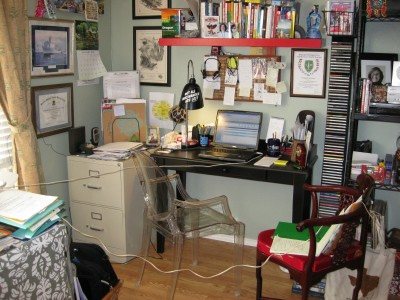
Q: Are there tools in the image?
A: No, there are no tools.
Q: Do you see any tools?
A: No, there are no tools.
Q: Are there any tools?
A: No, there are no tools.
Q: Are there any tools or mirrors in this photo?
A: No, there are no tools or mirrors.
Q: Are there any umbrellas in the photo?
A: No, there are no umbrellas.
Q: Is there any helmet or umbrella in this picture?
A: No, there are no umbrellas or helmets.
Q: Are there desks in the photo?
A: Yes, there is a desk.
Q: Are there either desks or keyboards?
A: Yes, there is a desk.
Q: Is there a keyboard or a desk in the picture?
A: Yes, there is a desk.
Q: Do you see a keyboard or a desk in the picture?
A: Yes, there is a desk.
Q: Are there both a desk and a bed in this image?
A: No, there is a desk but no beds.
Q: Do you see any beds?
A: No, there are no beds.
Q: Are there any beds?
A: No, there are no beds.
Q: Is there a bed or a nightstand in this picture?
A: No, there are no beds or nightstands.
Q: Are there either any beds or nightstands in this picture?
A: No, there are no beds or nightstands.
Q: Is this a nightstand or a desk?
A: This is a desk.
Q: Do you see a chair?
A: Yes, there is a chair.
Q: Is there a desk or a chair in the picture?
A: Yes, there is a chair.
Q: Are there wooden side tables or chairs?
A: Yes, there is a wood chair.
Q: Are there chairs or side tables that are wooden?
A: Yes, the chair is wooden.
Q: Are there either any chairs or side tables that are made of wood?
A: Yes, the chair is made of wood.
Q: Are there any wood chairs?
A: Yes, there is a wood chair.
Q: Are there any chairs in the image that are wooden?
A: Yes, there is a chair that is wooden.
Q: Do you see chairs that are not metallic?
A: Yes, there is a wooden chair.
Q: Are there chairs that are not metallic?
A: Yes, there is a wooden chair.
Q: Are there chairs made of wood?
A: Yes, there is a chair that is made of wood.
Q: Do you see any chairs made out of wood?
A: Yes, there is a chair that is made of wood.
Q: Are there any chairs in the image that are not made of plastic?
A: Yes, there is a chair that is made of wood.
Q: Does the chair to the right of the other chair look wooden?
A: Yes, the chair is wooden.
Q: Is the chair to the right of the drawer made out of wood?
A: Yes, the chair is made of wood.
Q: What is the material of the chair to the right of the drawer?
A: The chair is made of wood.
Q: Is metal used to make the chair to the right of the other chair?
A: No, the chair is made of wood.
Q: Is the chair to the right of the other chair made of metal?
A: No, the chair is made of wood.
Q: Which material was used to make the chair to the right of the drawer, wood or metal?
A: The chair is made of wood.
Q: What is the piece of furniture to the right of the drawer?
A: The piece of furniture is a chair.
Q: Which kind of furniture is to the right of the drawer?
A: The piece of furniture is a chair.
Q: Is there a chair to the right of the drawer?
A: Yes, there is a chair to the right of the drawer.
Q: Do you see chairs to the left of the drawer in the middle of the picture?
A: No, the chair is to the right of the drawer.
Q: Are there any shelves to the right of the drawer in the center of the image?
A: No, there is a chair to the right of the drawer.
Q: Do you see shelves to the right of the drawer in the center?
A: No, there is a chair to the right of the drawer.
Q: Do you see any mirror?
A: No, there are no mirrors.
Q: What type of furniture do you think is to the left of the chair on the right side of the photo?
A: The piece of furniture is a drawer.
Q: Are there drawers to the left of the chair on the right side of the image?
A: Yes, there is a drawer to the left of the chair.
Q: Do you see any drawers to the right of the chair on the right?
A: No, the drawer is to the left of the chair.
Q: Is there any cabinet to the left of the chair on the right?
A: No, there is a drawer to the left of the chair.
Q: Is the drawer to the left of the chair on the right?
A: Yes, the drawer is to the left of the chair.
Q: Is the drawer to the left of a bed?
A: No, the drawer is to the left of the chair.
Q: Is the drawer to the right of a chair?
A: No, the drawer is to the left of a chair.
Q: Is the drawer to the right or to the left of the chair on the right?
A: The drawer is to the left of the chair.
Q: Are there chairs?
A: Yes, there is a chair.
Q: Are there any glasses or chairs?
A: Yes, there is a chair.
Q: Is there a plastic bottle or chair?
A: Yes, there is a plastic chair.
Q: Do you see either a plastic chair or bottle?
A: Yes, there is a plastic chair.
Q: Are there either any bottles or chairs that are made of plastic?
A: Yes, the chair is made of plastic.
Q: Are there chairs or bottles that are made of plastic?
A: Yes, the chair is made of plastic.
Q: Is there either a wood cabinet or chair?
A: Yes, there is a wood chair.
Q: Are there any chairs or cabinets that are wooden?
A: Yes, the chair is wooden.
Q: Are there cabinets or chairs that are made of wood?
A: Yes, the chair is made of wood.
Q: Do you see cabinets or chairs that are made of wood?
A: Yes, the chair is made of wood.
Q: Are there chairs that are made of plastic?
A: Yes, there is a chair that is made of plastic.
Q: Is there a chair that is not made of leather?
A: Yes, there is a chair that is made of plastic.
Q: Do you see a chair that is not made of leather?
A: Yes, there is a chair that is made of plastic.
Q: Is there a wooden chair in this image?
A: Yes, there is a wood chair.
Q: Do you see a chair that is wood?
A: Yes, there is a wood chair.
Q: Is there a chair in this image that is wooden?
A: Yes, there is a chair that is wooden.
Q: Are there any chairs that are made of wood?
A: Yes, there is a chair that is made of wood.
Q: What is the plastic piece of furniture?
A: The piece of furniture is a chair.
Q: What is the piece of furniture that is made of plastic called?
A: The piece of furniture is a chair.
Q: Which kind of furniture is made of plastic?
A: The furniture is a chair.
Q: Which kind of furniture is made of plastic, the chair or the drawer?
A: The chair is made of plastic.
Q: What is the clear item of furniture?
A: The piece of furniture is a chair.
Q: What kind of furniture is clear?
A: The furniture is a chair.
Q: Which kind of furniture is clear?
A: The furniture is a chair.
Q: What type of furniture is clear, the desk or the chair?
A: The chair is clear.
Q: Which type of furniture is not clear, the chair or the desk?
A: The desk is not clear.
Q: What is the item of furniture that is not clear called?
A: The piece of furniture is a desk.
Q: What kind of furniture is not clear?
A: The furniture is a desk.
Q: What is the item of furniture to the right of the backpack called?
A: The piece of furniture is a chair.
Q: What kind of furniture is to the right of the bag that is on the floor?
A: The piece of furniture is a chair.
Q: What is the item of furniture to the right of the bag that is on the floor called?
A: The piece of furniture is a chair.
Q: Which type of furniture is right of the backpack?
A: The piece of furniture is a chair.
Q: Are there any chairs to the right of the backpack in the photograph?
A: Yes, there is a chair to the right of the backpack.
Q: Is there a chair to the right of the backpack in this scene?
A: Yes, there is a chair to the right of the backpack.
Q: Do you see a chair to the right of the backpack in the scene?
A: Yes, there is a chair to the right of the backpack.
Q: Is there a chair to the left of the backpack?
A: No, the chair is to the right of the backpack.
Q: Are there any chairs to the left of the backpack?
A: No, the chair is to the right of the backpack.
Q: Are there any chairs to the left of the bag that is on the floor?
A: No, the chair is to the right of the backpack.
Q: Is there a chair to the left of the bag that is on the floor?
A: No, the chair is to the right of the backpack.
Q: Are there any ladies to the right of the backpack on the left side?
A: No, there is a chair to the right of the backpack.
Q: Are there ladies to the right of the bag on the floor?
A: No, there is a chair to the right of the backpack.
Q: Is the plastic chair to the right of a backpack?
A: Yes, the chair is to the right of a backpack.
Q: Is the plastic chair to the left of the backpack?
A: No, the chair is to the right of the backpack.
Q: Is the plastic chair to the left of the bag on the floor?
A: No, the chair is to the right of the backpack.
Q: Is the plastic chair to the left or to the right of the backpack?
A: The chair is to the right of the backpack.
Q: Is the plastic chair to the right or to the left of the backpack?
A: The chair is to the right of the backpack.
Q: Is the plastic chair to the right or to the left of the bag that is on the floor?
A: The chair is to the right of the backpack.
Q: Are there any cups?
A: Yes, there is a cup.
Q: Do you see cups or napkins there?
A: Yes, there is a cup.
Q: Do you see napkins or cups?
A: Yes, there is a cup.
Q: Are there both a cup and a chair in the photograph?
A: Yes, there are both a cup and a chair.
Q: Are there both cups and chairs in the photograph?
A: Yes, there are both a cup and a chair.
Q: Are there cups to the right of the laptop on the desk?
A: Yes, there is a cup to the right of the laptop.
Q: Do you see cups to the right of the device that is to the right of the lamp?
A: Yes, there is a cup to the right of the laptop.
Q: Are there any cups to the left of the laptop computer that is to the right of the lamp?
A: No, the cup is to the right of the laptop.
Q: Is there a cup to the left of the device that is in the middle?
A: No, the cup is to the right of the laptop.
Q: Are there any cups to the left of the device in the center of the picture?
A: No, the cup is to the right of the laptop.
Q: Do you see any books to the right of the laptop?
A: No, there is a cup to the right of the laptop.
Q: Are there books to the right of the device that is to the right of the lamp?
A: No, there is a cup to the right of the laptop.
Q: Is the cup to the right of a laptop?
A: Yes, the cup is to the right of a laptop.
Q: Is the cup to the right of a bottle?
A: No, the cup is to the right of a laptop.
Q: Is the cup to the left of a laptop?
A: No, the cup is to the right of a laptop.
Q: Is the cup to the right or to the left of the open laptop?
A: The cup is to the right of the laptop.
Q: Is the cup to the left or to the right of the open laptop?
A: The cup is to the right of the laptop.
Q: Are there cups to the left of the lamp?
A: No, the cup is to the right of the lamp.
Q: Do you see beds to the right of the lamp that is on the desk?
A: No, there is a cup to the right of the lamp.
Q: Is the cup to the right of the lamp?
A: Yes, the cup is to the right of the lamp.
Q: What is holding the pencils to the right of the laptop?
A: The cup is holding the pencils.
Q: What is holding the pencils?
A: The cup is holding the pencils.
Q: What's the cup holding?
A: The cup is holding the pencils.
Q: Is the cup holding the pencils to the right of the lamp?
A: Yes, the cup is holding the pencils.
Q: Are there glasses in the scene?
A: No, there are no glasses.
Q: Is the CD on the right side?
A: Yes, the CD is on the right of the image.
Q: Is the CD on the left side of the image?
A: No, the CD is on the right of the image.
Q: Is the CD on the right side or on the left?
A: The CD is on the right of the image.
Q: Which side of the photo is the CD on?
A: The CD is on the right of the image.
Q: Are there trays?
A: No, there are no trays.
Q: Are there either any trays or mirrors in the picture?
A: No, there are no trays or mirrors.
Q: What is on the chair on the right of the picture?
A: The seat is on the chair.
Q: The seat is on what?
A: The seat is on the chair.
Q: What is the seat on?
A: The seat is on the chair.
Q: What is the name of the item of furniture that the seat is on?
A: The piece of furniture is a chair.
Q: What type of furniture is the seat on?
A: The seat is on the chair.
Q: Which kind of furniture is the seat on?
A: The seat is on the chair.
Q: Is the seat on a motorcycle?
A: No, the seat is on the chair.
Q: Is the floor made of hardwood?
A: Yes, the floor is made of hardwood.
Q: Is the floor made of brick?
A: No, the floor is made of hardwood.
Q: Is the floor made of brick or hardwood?
A: The floor is made of hardwood.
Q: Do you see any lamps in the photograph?
A: Yes, there is a lamp.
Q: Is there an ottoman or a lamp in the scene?
A: Yes, there is a lamp.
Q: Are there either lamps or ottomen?
A: Yes, there is a lamp.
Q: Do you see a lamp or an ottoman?
A: Yes, there is a lamp.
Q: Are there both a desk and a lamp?
A: Yes, there are both a lamp and a desk.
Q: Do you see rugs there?
A: No, there are no rugs.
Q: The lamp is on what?
A: The lamp is on the desk.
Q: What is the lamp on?
A: The lamp is on the desk.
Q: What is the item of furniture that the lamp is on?
A: The piece of furniture is a desk.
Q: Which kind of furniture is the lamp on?
A: The lamp is on the desk.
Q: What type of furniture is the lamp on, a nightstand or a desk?
A: The lamp is on a desk.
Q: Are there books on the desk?
A: No, there is a lamp on the desk.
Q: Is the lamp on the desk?
A: Yes, the lamp is on the desk.